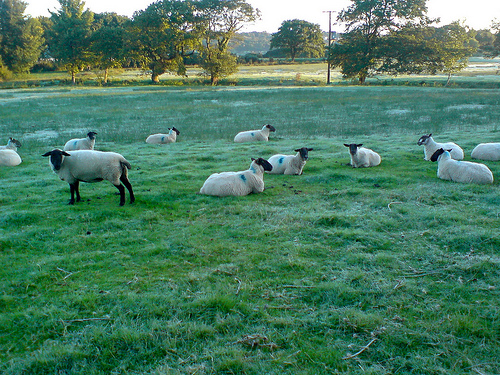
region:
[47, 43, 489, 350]
sheep in a field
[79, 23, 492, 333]
sheep in an area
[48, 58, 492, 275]
sheep that have been marked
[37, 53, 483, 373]
sheep that have been spray painted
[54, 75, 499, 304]
sheep laying in a field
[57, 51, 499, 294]
sheep laying on the grass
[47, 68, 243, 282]
a sheep standing in a field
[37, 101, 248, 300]
a sheep standing on the grass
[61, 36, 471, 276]
an area with sheeps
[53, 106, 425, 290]
an area of sheep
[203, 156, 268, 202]
sheep lying in grass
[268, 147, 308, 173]
sheep lying in grass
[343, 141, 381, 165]
sheep lying in grass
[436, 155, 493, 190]
sheep lying in grass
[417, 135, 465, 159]
sheep lying in grass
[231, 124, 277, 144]
sheep lying in grass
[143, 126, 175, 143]
sheep lying in grass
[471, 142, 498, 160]
sheep lying in grass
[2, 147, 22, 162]
sheep lying in grass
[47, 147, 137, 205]
sheep standing in grass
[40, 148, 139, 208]
a sheep with black face and legs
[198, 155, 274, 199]
a resting sheep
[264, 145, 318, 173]
a sheep lying down but head up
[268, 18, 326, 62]
a tree with green leaves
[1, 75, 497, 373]
a grassy green field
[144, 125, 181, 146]
a sheep with a blue mark on it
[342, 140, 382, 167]
a sheep with ears raised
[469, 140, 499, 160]
the back of a sheep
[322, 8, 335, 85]
a tall pole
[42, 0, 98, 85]
a bushy tall tree